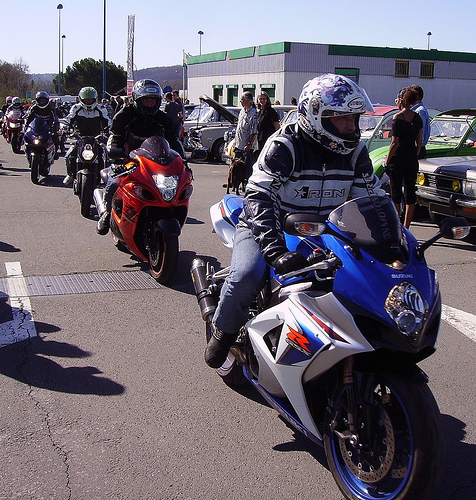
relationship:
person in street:
[234, 93, 260, 166] [4, 119, 469, 499]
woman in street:
[384, 89, 422, 231] [4, 119, 469, 499]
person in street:
[257, 89, 282, 140] [4, 119, 469, 499]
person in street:
[160, 93, 179, 121] [4, 119, 469, 499]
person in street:
[25, 91, 60, 184] [4, 119, 469, 499]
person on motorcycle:
[25, 91, 60, 184] [21, 126, 59, 184]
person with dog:
[234, 93, 260, 166] [224, 157, 252, 191]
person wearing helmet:
[102, 82, 195, 228] [135, 80, 160, 113]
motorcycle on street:
[100, 126, 193, 279] [4, 119, 469, 499]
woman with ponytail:
[384, 89, 421, 220] [406, 92, 419, 105]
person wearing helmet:
[203, 76, 405, 388] [296, 64, 377, 161]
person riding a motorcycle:
[25, 91, 65, 162] [21, 126, 59, 184]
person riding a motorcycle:
[203, 76, 405, 388] [197, 183, 441, 484]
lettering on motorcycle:
[290, 322, 314, 351] [197, 183, 441, 484]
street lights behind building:
[54, 0, 215, 104] [190, 37, 475, 124]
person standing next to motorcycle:
[234, 93, 260, 166] [21, 126, 59, 184]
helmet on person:
[296, 64, 377, 161] [203, 76, 405, 388]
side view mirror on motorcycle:
[285, 209, 323, 242] [197, 183, 441, 484]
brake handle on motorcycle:
[278, 265, 327, 288] [197, 183, 441, 484]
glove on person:
[275, 240, 307, 269] [203, 76, 405, 388]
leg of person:
[198, 207, 265, 342] [203, 76, 405, 388]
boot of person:
[204, 331, 237, 367] [203, 76, 405, 388]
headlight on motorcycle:
[389, 283, 425, 341] [197, 183, 441, 484]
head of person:
[238, 89, 261, 107] [234, 93, 260, 166]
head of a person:
[254, 90, 274, 109] [257, 89, 282, 140]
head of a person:
[33, 91, 54, 108] [25, 91, 60, 184]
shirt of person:
[231, 111, 258, 148] [234, 93, 260, 166]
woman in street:
[384, 89, 422, 231] [23, 184, 219, 465]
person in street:
[234, 93, 260, 166] [23, 184, 219, 465]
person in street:
[257, 89, 282, 140] [23, 184, 219, 465]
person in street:
[160, 93, 179, 121] [23, 184, 219, 465]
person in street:
[25, 91, 60, 184] [23, 184, 219, 465]